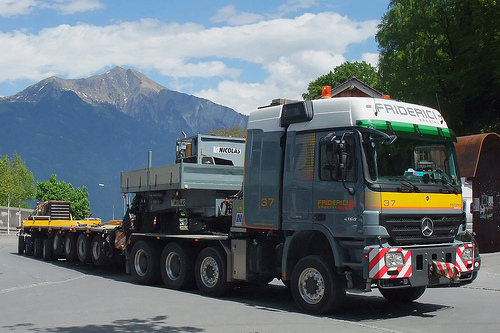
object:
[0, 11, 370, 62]
clouds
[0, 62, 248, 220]
mountain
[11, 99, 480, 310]
truck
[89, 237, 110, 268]
wheel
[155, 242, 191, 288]
wheel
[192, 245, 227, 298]
wheel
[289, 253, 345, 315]
wheel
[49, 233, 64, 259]
wheel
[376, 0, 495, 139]
tree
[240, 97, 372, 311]
side angle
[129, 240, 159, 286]
wheel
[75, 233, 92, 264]
wheel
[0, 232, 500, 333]
ground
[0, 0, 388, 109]
blue sky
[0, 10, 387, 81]
white clouds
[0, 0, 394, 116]
sky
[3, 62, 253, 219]
mountain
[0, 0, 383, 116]
clouds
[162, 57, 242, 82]
clouds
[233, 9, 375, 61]
clouds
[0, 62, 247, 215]
mountain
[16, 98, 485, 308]
truck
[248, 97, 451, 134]
top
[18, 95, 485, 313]
truck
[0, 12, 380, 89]
clouds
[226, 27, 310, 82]
clouds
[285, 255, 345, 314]
wheel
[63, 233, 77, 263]
wheel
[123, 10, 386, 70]
clouds